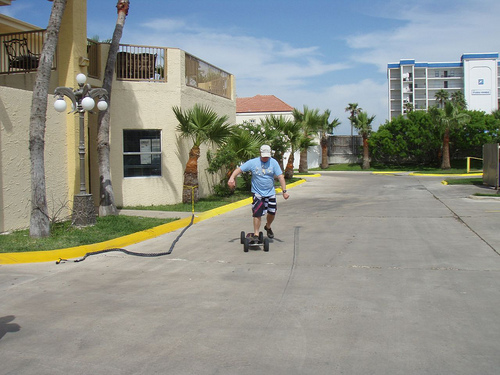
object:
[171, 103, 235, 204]
tree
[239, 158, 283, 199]
shirt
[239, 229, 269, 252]
skateboard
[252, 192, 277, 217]
shorts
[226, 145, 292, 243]
man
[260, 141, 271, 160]
cap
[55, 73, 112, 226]
lamp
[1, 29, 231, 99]
railing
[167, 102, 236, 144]
leaves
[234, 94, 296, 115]
shingles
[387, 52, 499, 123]
building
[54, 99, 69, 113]
light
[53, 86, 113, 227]
pole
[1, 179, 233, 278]
curb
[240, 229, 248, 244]
wheel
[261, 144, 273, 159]
hat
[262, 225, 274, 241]
shoe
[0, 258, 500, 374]
concrete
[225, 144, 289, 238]
person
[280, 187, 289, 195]
watch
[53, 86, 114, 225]
post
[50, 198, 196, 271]
hose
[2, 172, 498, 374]
street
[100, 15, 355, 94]
cloud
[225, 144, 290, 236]
boy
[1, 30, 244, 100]
balcony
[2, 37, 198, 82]
furniture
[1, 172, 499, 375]
road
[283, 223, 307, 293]
skid mark